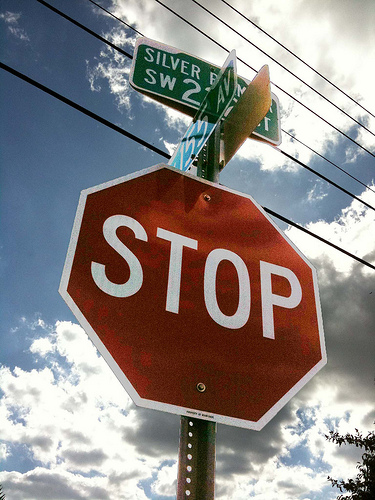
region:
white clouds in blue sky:
[24, 377, 63, 449]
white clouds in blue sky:
[80, 422, 129, 493]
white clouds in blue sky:
[263, 453, 299, 494]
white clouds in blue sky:
[348, 337, 360, 363]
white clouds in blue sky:
[17, 257, 42, 313]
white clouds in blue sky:
[42, 115, 69, 153]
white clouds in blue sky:
[307, 26, 347, 80]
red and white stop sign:
[62, 156, 326, 433]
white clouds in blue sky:
[218, 13, 294, 45]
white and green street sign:
[130, 31, 285, 175]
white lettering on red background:
[83, 201, 299, 344]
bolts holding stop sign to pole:
[194, 185, 211, 393]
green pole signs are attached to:
[176, 108, 229, 498]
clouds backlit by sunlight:
[3, 333, 131, 470]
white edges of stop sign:
[56, 154, 329, 431]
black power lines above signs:
[1, 1, 370, 270]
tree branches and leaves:
[325, 433, 373, 491]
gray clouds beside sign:
[314, 251, 373, 405]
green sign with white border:
[127, 37, 285, 149]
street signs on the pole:
[33, 17, 289, 498]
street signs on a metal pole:
[96, 12, 257, 489]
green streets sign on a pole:
[71, 8, 359, 250]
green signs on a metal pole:
[85, 19, 329, 184]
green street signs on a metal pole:
[118, 25, 293, 200]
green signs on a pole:
[110, 21, 256, 186]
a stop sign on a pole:
[28, 118, 331, 436]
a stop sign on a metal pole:
[39, 132, 349, 493]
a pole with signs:
[88, 9, 364, 215]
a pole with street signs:
[81, 27, 320, 231]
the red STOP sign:
[56, 162, 327, 432]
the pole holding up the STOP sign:
[176, 415, 215, 499]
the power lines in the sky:
[0, 0, 373, 268]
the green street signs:
[129, 35, 281, 173]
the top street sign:
[129, 36, 282, 146]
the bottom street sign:
[167, 49, 237, 172]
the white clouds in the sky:
[1, 1, 374, 499]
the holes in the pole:
[184, 420, 193, 495]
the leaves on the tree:
[322, 415, 373, 498]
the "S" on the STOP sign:
[90, 213, 147, 297]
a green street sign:
[131, 34, 281, 143]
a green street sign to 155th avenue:
[165, 46, 232, 166]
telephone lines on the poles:
[291, 49, 373, 245]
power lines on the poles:
[280, 33, 373, 234]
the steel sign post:
[178, 416, 217, 499]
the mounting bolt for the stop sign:
[196, 379, 206, 395]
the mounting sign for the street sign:
[190, 152, 196, 160]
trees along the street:
[327, 426, 374, 498]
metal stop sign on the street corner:
[58, 161, 326, 429]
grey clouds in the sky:
[0, 414, 177, 498]